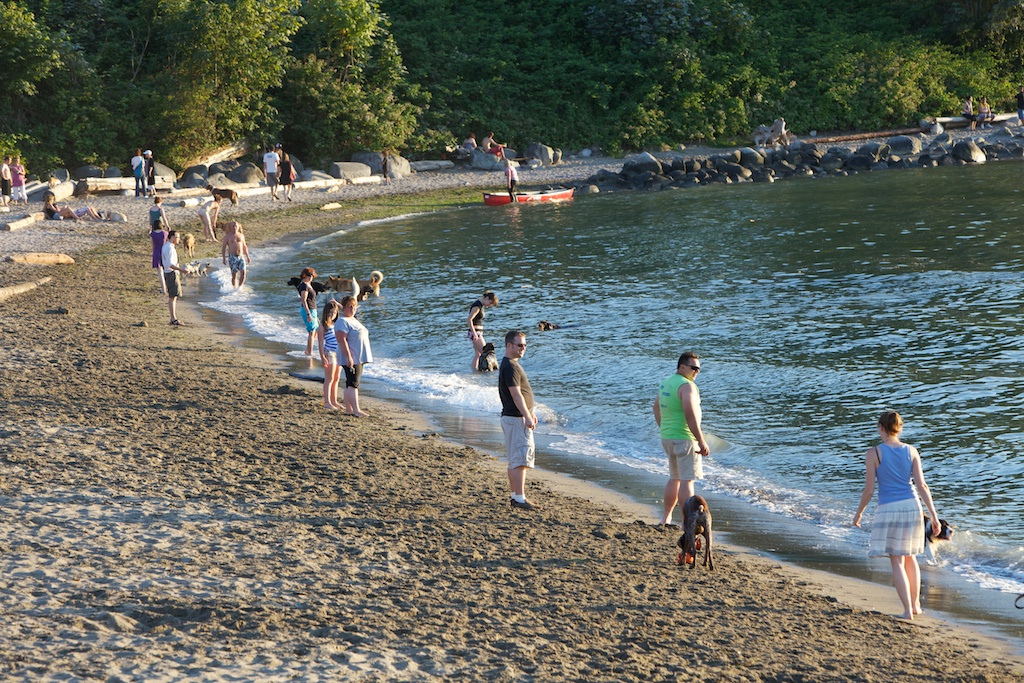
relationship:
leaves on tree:
[751, 7, 866, 103] [464, 5, 780, 172]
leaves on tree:
[752, 7, 835, 103] [598, 9, 953, 157]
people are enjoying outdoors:
[91, 202, 990, 683] [20, 205, 971, 640]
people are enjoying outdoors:
[154, 269, 952, 453] [84, 222, 975, 683]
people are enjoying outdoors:
[162, 233, 1009, 674] [264, 291, 941, 683]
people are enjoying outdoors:
[132, 306, 694, 564] [30, 254, 1005, 596]